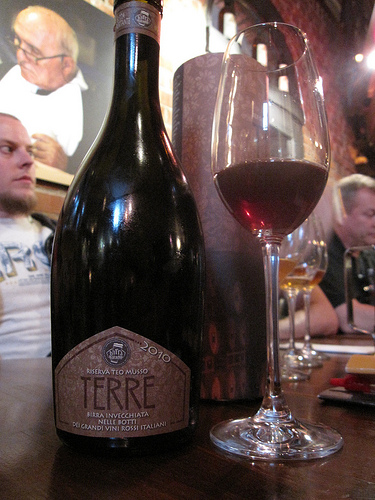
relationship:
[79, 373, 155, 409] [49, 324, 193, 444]
terre on label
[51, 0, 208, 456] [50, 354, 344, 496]
black bottle on table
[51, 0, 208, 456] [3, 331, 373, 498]
black bottle on table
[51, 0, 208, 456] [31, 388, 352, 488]
black bottle on table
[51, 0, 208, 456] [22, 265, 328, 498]
black bottle on table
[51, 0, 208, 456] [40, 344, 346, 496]
black bottle on table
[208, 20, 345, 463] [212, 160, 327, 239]
glass on wine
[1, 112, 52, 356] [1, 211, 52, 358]
man wearing shirt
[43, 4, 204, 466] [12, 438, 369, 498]
wine in table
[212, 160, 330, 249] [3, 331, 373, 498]
wine in table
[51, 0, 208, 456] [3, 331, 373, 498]
black bottle in table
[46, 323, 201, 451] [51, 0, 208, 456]
label on black bottle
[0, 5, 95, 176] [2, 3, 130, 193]
man on screen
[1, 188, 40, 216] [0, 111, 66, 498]
beard on man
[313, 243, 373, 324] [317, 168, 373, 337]
shirt on man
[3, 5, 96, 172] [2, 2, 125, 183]
man on painting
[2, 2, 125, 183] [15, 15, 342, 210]
painting on wall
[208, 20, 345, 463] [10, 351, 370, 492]
glass on table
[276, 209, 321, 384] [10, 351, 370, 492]
glass on table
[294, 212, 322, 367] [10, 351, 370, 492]
glass on table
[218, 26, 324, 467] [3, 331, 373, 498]
wine on table